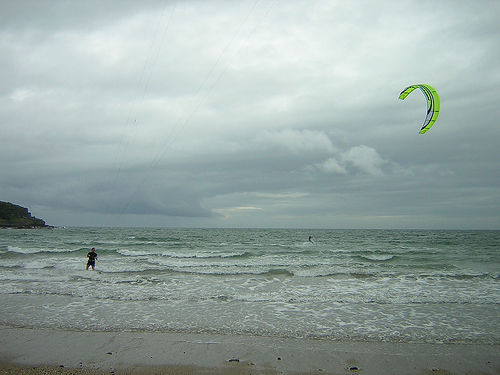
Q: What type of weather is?
A: It is cloudy.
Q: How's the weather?
A: It is cloudy.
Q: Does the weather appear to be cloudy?
A: Yes, it is cloudy.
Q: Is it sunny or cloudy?
A: It is cloudy.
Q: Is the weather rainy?
A: No, it is cloudy.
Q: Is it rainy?
A: No, it is cloudy.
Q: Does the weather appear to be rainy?
A: No, it is cloudy.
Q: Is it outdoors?
A: Yes, it is outdoors.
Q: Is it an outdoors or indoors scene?
A: It is outdoors.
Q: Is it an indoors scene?
A: No, it is outdoors.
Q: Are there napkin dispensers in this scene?
A: No, there are no napkin dispensers.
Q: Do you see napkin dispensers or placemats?
A: No, there are no napkin dispensers or placemats.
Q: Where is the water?
A: The water is on the sand.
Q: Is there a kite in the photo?
A: Yes, there is a kite.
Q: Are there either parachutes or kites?
A: Yes, there is a kite.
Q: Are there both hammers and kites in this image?
A: No, there is a kite but no hammers.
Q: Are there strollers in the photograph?
A: No, there are no strollers.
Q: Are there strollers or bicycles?
A: No, there are no strollers or bicycles.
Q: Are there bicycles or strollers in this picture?
A: No, there are no strollers or bicycles.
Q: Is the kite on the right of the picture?
A: Yes, the kite is on the right of the image.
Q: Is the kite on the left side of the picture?
A: No, the kite is on the right of the image.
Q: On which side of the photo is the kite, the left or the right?
A: The kite is on the right of the image.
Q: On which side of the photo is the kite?
A: The kite is on the right of the image.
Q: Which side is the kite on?
A: The kite is on the right of the image.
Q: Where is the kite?
A: The kite is in the sky.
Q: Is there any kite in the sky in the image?
A: Yes, there is a kite in the sky.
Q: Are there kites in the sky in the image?
A: Yes, there is a kite in the sky.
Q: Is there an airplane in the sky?
A: No, there is a kite in the sky.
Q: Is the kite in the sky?
A: Yes, the kite is in the sky.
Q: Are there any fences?
A: No, there are no fences.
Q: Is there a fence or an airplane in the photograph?
A: No, there are no fences or airplanes.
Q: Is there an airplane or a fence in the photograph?
A: No, there are no fences or airplanes.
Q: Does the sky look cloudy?
A: Yes, the sky is cloudy.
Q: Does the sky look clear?
A: No, the sky is cloudy.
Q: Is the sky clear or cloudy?
A: The sky is cloudy.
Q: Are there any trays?
A: No, there are no trays.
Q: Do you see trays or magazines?
A: No, there are no trays or magazines.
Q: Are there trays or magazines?
A: No, there are no trays or magazines.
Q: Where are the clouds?
A: The clouds are in the sky.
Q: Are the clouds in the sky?
A: Yes, the clouds are in the sky.